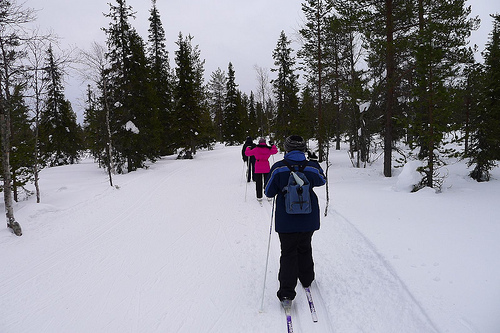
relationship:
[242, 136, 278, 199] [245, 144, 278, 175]
skier wearing coat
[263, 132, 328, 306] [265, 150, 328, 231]
skier wearing coat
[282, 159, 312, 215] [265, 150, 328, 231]
backpack matches coat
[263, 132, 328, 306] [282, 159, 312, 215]
skier carrying backpack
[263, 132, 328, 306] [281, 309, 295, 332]
skier wearing ski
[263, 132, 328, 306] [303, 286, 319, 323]
skier wearing ski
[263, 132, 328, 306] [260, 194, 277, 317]
skier holding pole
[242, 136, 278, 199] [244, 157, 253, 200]
skier holding pole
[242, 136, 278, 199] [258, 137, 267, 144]
skier wearing cap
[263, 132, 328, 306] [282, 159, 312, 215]
skier has backpack